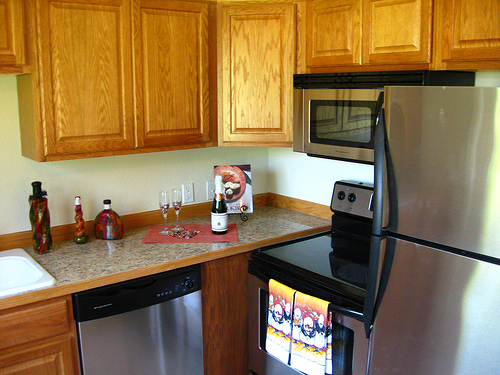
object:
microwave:
[291, 88, 386, 165]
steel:
[291, 87, 391, 163]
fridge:
[362, 82, 500, 375]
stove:
[243, 175, 376, 375]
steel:
[245, 269, 370, 375]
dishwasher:
[73, 263, 207, 374]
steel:
[77, 285, 206, 374]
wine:
[209, 173, 229, 235]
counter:
[0, 191, 337, 311]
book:
[212, 162, 254, 216]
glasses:
[158, 189, 175, 236]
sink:
[0, 245, 59, 301]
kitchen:
[0, 3, 496, 371]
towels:
[288, 290, 339, 374]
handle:
[246, 259, 365, 320]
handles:
[361, 235, 386, 339]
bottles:
[72, 195, 90, 245]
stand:
[240, 204, 249, 225]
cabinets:
[14, 0, 221, 164]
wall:
[0, 0, 500, 239]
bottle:
[27, 180, 56, 255]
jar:
[94, 198, 124, 240]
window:
[307, 98, 377, 150]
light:
[315, 106, 371, 144]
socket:
[182, 182, 194, 204]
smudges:
[422, 154, 451, 178]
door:
[366, 83, 500, 375]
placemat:
[141, 222, 240, 243]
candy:
[160, 200, 183, 214]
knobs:
[347, 193, 356, 203]